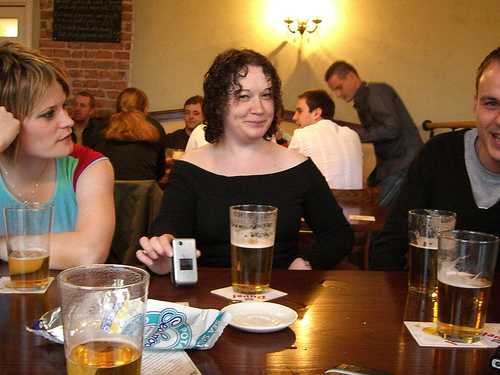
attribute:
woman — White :
[135, 46, 353, 273]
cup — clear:
[219, 191, 308, 310]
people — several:
[21, 56, 495, 268]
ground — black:
[450, 174, 454, 178]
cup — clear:
[225, 196, 297, 297]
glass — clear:
[228, 202, 280, 297]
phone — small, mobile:
[173, 239, 200, 284]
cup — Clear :
[49, 258, 152, 372]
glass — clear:
[386, 194, 445, 292]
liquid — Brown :
[15, 252, 26, 278]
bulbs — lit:
[255, 0, 349, 52]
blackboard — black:
[49, 0, 122, 45]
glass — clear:
[226, 196, 280, 295]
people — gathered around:
[323, 59, 421, 206]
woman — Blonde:
[6, 42, 124, 287]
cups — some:
[15, 197, 477, 356]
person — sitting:
[125, 28, 388, 260]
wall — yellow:
[388, 17, 467, 74]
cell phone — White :
[130, 190, 234, 327]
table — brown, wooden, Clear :
[0, 269, 499, 372]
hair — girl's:
[199, 40, 289, 137]